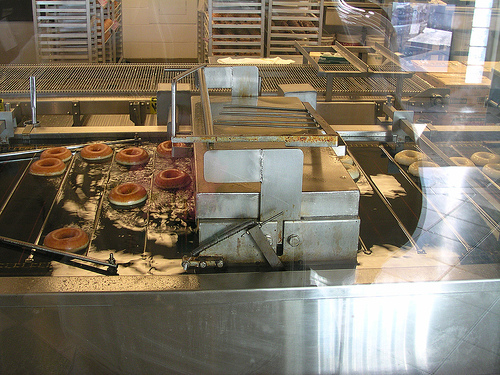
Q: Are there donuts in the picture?
A: Yes, there is a donut.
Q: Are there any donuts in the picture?
A: Yes, there is a donut.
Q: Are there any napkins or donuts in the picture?
A: Yes, there is a donut.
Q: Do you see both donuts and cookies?
A: No, there is a donut but no cookies.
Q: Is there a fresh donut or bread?
A: Yes, there is a fresh donut.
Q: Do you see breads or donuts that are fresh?
A: Yes, the donut is fresh.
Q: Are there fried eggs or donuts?
A: Yes, there is a fried donut.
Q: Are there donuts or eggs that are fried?
A: Yes, the donut is fried.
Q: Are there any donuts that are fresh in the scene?
A: Yes, there is a fresh donut.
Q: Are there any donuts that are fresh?
A: Yes, there is a donut that is fresh.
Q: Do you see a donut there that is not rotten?
A: Yes, there is a fresh donut.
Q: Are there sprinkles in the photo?
A: No, there are no sprinkles.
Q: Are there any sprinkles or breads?
A: No, there are no sprinkles or breads.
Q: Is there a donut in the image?
A: Yes, there is a donut.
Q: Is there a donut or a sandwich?
A: Yes, there is a donut.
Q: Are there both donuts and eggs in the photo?
A: No, there is a donut but no eggs.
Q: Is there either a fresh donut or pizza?
A: Yes, there is a fresh donut.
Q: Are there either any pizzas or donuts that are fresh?
A: Yes, the donut is fresh.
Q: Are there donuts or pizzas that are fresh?
A: Yes, the donut is fresh.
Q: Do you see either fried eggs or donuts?
A: Yes, there is a fried donut.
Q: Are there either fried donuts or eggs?
A: Yes, there is a fried donut.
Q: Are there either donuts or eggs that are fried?
A: Yes, the donut is fried.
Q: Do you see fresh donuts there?
A: Yes, there is a fresh donut.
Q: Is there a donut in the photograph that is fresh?
A: Yes, there is a donut that is fresh.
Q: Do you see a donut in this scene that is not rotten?
A: Yes, there is a fresh donut.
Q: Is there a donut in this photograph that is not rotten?
A: Yes, there is a fresh donut.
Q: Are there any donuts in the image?
A: Yes, there is a donut.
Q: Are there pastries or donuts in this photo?
A: Yes, there is a donut.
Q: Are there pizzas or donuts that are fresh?
A: Yes, the donut is fresh.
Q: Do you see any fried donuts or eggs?
A: Yes, there is a fried donut.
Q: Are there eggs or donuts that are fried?
A: Yes, the donut is fried.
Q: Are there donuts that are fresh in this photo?
A: Yes, there is a fresh donut.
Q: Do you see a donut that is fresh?
A: Yes, there is a donut that is fresh.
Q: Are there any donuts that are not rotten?
A: Yes, there is a fresh donut.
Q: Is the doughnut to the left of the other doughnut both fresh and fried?
A: Yes, the doughnut is fresh and fried.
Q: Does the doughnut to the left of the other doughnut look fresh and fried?
A: Yes, the doughnut is fresh and fried.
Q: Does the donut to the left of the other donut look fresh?
A: Yes, the doughnut is fresh.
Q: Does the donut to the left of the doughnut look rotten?
A: No, the doughnut is fresh.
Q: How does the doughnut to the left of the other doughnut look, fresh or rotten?
A: The donut is fresh.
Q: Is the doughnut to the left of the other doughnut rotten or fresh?
A: The donut is fresh.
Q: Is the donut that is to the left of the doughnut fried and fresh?
A: Yes, the donut is fried and fresh.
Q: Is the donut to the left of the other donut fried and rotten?
A: No, the donut is fried but fresh.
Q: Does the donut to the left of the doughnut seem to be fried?
A: Yes, the doughnut is fried.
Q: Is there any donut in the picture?
A: Yes, there is a donut.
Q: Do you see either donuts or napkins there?
A: Yes, there is a donut.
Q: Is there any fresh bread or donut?
A: Yes, there is a fresh donut.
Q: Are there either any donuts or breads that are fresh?
A: Yes, the donut is fresh.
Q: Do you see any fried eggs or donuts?
A: Yes, there is a fried donut.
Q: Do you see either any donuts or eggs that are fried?
A: Yes, the donut is fried.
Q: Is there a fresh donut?
A: Yes, there is a fresh donut.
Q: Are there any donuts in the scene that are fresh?
A: Yes, there is a donut that is fresh.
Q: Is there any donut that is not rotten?
A: Yes, there is a fresh donut.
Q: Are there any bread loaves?
A: No, there are no bread loaves.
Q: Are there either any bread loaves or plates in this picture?
A: No, there are no bread loaves or plates.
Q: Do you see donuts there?
A: Yes, there is a donut.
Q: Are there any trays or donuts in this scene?
A: Yes, there is a donut.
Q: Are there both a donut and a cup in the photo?
A: No, there is a donut but no cups.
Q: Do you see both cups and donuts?
A: No, there is a donut but no cups.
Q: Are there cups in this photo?
A: No, there are no cups.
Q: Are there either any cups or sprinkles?
A: No, there are no cups or sprinkles.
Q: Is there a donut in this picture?
A: Yes, there is a donut.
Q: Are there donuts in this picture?
A: Yes, there is a donut.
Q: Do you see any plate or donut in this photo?
A: Yes, there is a donut.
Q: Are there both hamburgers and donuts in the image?
A: No, there is a donut but no hamburgers.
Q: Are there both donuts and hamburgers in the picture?
A: No, there is a donut but no hamburgers.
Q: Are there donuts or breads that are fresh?
A: Yes, the donut is fresh.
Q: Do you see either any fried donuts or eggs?
A: Yes, there is a fried donut.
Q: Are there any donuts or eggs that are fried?
A: Yes, the donut is fried.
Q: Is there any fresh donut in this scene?
A: Yes, there is a fresh donut.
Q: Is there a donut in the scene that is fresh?
A: Yes, there is a donut that is fresh.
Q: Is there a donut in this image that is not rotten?
A: Yes, there is a fresh donut.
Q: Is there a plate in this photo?
A: No, there are no plates.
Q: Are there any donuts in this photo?
A: Yes, there is a donut.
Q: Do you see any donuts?
A: Yes, there is a donut.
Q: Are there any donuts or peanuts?
A: Yes, there is a donut.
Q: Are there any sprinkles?
A: No, there are no sprinkles.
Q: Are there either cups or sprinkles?
A: No, there are no sprinkles or cups.